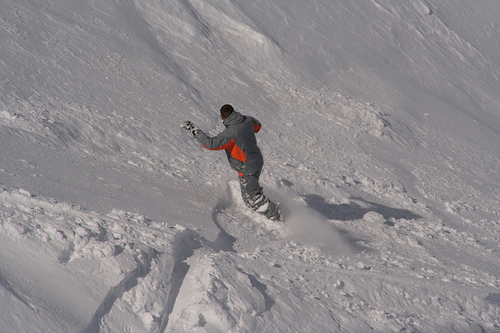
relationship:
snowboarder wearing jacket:
[180, 104, 282, 221] [196, 113, 265, 174]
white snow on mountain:
[0, 1, 498, 332] [1, 0, 500, 332]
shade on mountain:
[296, 193, 425, 226] [1, 0, 500, 332]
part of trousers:
[236, 169, 282, 221] [237, 169, 282, 221]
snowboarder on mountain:
[180, 104, 282, 221] [1, 0, 500, 332]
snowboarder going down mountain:
[180, 104, 282, 221] [1, 0, 500, 332]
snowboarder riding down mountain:
[180, 104, 282, 221] [1, 0, 500, 332]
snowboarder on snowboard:
[180, 104, 282, 221] [230, 180, 347, 252]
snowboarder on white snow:
[180, 104, 282, 221] [0, 1, 498, 332]